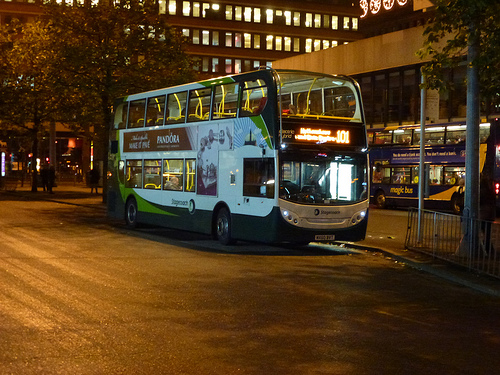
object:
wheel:
[209, 200, 229, 246]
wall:
[273, 17, 500, 76]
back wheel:
[123, 193, 140, 226]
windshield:
[282, 154, 371, 204]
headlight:
[282, 210, 289, 217]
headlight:
[360, 211, 367, 217]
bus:
[108, 65, 373, 246]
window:
[184, 157, 196, 193]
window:
[161, 158, 183, 190]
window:
[141, 158, 161, 188]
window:
[208, 81, 238, 121]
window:
[123, 157, 142, 188]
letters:
[300, 127, 332, 135]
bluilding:
[270, 16, 498, 130]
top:
[113, 66, 366, 130]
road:
[1, 191, 500, 375]